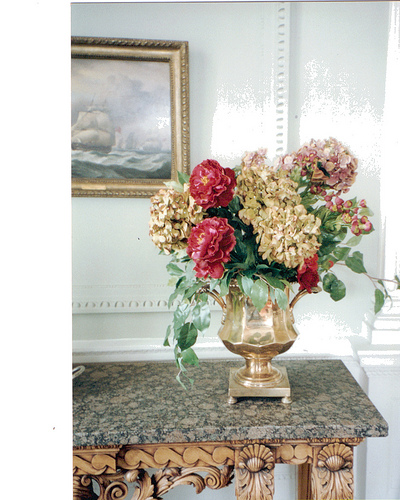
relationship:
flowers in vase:
[148, 135, 399, 393] [186, 275, 323, 405]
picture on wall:
[72, 57, 174, 181] [72, 2, 399, 361]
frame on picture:
[72, 35, 192, 199] [72, 57, 174, 181]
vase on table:
[186, 275, 323, 405] [70, 358, 389, 499]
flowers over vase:
[148, 135, 399, 393] [186, 275, 323, 405]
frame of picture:
[72, 35, 192, 199] [72, 57, 174, 181]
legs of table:
[237, 437, 355, 499] [70, 358, 389, 499]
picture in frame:
[72, 57, 174, 181] [72, 35, 192, 199]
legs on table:
[237, 437, 355, 499] [70, 358, 389, 499]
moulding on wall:
[72, 1, 292, 316] [72, 2, 399, 361]